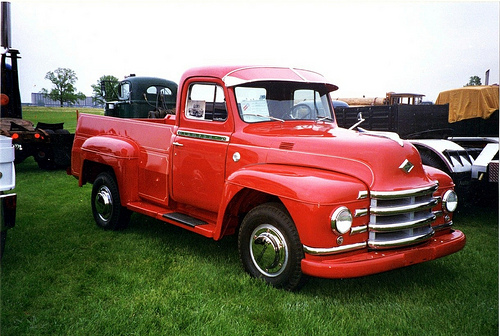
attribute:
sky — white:
[186, 10, 306, 60]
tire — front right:
[237, 197, 307, 292]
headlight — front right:
[326, 203, 356, 238]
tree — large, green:
[40, 67, 86, 106]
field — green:
[16, 105, 493, 329]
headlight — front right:
[443, 185, 459, 210]